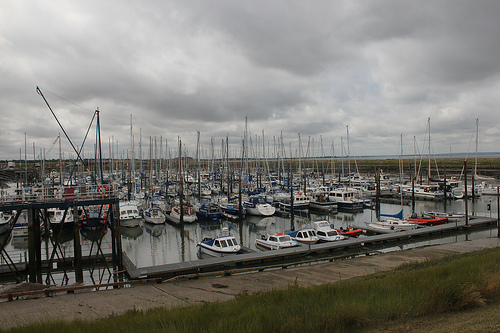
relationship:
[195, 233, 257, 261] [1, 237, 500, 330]
boat at harbor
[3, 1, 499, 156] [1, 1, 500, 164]
clouds in sky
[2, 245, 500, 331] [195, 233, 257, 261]
grass in front of boat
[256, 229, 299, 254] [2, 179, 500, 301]
boat in water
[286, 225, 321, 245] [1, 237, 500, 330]
boat in harbor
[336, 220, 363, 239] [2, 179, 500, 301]
boat in water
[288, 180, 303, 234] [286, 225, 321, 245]
pole on boat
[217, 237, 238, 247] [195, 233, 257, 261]
windows on boat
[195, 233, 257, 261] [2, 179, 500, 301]
boat in water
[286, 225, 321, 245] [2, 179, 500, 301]
boat in water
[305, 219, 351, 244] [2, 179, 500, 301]
boat in water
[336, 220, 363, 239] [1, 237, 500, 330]
boat in harbor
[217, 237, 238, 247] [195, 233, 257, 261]
windows of boat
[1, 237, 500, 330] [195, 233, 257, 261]
harbor holding boat